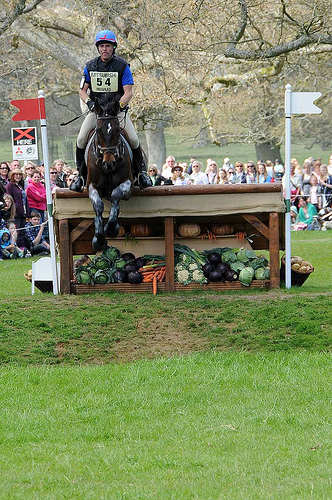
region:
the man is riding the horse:
[87, 32, 133, 177]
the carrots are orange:
[144, 267, 160, 285]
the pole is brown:
[166, 182, 228, 196]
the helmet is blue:
[91, 29, 121, 49]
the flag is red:
[8, 89, 48, 123]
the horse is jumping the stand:
[81, 98, 118, 253]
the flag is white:
[283, 76, 321, 118]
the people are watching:
[176, 154, 261, 184]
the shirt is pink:
[28, 186, 43, 203]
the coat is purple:
[8, 184, 21, 208]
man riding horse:
[62, 25, 154, 246]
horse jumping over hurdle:
[17, 77, 316, 311]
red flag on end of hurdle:
[12, 57, 132, 301]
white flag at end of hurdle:
[224, 54, 324, 308]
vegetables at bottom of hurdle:
[41, 175, 303, 312]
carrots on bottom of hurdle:
[122, 241, 184, 302]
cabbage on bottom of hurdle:
[202, 227, 291, 313]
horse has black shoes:
[72, 191, 135, 260]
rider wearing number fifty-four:
[69, 24, 139, 121]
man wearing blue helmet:
[78, 19, 126, 64]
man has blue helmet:
[88, 32, 121, 50]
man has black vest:
[79, 53, 134, 86]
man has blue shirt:
[119, 70, 142, 88]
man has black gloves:
[74, 104, 113, 122]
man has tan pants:
[62, 103, 144, 183]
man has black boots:
[75, 143, 91, 178]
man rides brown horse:
[76, 112, 145, 232]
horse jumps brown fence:
[31, 105, 172, 241]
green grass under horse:
[39, 308, 291, 484]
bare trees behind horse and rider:
[5, 6, 323, 138]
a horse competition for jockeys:
[15, 25, 262, 249]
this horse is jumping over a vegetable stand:
[37, 173, 329, 326]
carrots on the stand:
[134, 266, 169, 297]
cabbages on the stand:
[73, 253, 116, 294]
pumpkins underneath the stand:
[174, 220, 243, 239]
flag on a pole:
[1, 93, 52, 160]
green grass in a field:
[7, 361, 306, 477]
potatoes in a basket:
[279, 248, 313, 290]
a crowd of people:
[155, 148, 279, 180]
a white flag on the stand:
[262, 55, 326, 138]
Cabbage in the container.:
[222, 243, 271, 283]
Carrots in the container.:
[140, 260, 165, 292]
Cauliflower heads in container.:
[174, 252, 205, 287]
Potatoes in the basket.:
[280, 251, 313, 285]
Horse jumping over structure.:
[68, 89, 160, 253]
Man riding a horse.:
[76, 27, 142, 250]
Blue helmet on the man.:
[92, 26, 118, 62]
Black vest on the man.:
[76, 28, 133, 119]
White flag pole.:
[281, 84, 321, 288]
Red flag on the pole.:
[8, 89, 62, 294]